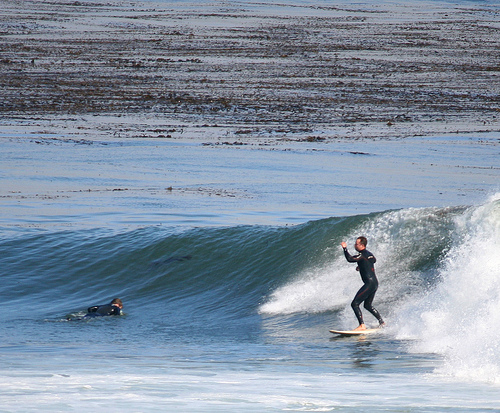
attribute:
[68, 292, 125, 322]
dummy — rescue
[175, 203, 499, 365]
waves — white, blue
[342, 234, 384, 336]
man — surfing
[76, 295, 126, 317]
man — surfing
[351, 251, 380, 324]
wetsuit — black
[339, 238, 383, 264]
arms — man's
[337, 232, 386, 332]
man — surfing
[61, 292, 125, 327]
man — surfing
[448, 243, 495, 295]
foam — white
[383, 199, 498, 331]
wave — crashing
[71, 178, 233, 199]
weed — sea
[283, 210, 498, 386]
spray — white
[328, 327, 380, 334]
board — white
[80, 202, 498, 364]
waves — ocean, white, blue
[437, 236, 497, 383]
foam — white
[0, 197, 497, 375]
wave — crashing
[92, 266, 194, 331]
dog — dark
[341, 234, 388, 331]
surfer — male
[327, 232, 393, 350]
suit — black, wet, mens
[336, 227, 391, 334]
surfer — adult, white, male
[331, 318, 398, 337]
surfboard — white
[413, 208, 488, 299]
waves — blue, white, ocean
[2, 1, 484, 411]
ocean — surface, blue, white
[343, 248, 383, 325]
wetsuit — black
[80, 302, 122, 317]
wetsuit — black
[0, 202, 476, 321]
wave — large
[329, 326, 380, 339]
surfboard — white